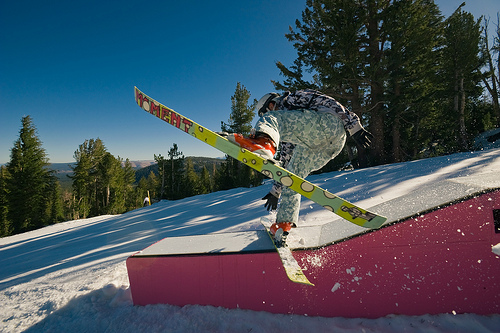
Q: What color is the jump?
A: Pink.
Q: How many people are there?
A: One.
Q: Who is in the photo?
A: A skier.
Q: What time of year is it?
A: Winter.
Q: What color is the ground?
A: White.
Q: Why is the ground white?
A: Snow.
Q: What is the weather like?
A: Cold.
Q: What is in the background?
A: Trees.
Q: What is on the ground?
A: Snow.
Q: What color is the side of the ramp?
A: Pink.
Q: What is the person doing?
A: A stunt on skis.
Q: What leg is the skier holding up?
A: Left.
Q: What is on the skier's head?
A: A helmet.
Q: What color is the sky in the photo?
A: Blue.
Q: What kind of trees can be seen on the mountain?
A: Pine trees.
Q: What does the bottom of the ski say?
A: MOMENT.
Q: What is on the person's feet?
A: Skis.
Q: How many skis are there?
A: Two.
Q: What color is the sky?
A: Blue.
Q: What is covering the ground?
A: Snow.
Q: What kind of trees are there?
A: Evergreen trees.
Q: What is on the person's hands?
A: Gloves.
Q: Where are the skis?
A: On the person's feet.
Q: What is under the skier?
A: A ramp.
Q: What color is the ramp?
A: Pink.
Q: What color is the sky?
A: Blue.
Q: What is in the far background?
A: Mountains.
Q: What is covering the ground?
A: Snow.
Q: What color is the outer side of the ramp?
A: Pink.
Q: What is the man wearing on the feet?
A: Skis.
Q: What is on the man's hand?
A: Glove.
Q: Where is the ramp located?
A: On top of mountain.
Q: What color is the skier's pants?
A: Camouflage.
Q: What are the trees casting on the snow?
A: Shadows.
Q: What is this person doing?
A: Skiing.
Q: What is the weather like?
A: Clear and sunny.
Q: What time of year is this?
A: Winter.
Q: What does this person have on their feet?
A: Skis.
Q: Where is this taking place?
A: Ski ramp.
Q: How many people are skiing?
A: 1.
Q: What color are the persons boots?
A: Red.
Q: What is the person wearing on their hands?
A: Gloves.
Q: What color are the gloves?
A: Black.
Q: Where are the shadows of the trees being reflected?
A: On the snow.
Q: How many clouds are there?
A: None.